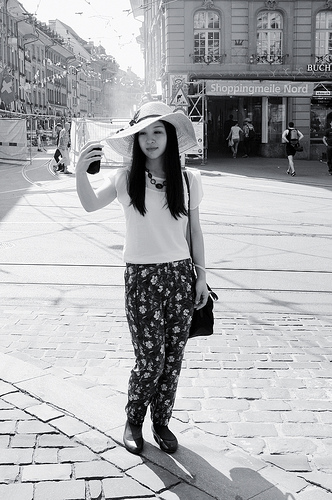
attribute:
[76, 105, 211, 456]
woman — tourist, taking a selfie, posing, taking selfie, outdoors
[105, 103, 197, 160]
hat — straw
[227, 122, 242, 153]
person — shopping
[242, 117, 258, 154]
person — shopping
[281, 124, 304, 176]
person — shopping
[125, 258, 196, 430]
pants — flowery, flowered print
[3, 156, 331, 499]
plaza — main, cobble stone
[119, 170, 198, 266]
blouse — feminine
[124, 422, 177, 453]
shoes — dull, leather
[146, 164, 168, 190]
necklace — bulky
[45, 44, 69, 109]
flag — large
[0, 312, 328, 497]
street — bricks